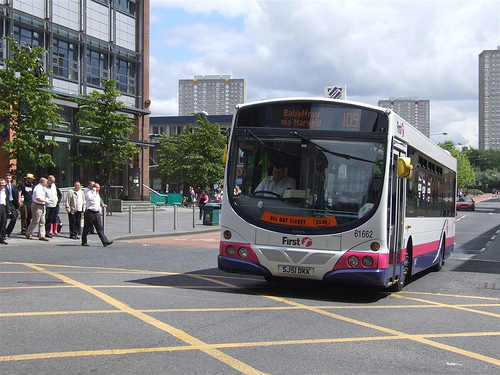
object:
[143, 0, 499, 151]
clouds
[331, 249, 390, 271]
stripes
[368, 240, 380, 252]
headlight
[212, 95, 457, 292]
bus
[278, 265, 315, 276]
plate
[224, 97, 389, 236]
windshield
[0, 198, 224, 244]
crosswalk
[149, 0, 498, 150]
sky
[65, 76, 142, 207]
trees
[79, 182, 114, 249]
people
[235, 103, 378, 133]
lcd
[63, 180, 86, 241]
people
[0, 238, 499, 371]
road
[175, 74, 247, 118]
building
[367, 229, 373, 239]
numbers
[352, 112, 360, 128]
numbers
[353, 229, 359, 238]
numbers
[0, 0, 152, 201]
building